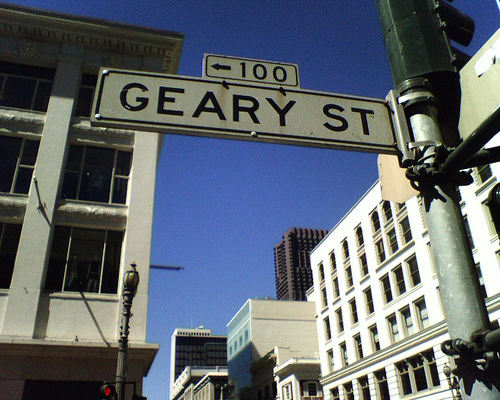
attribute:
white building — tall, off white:
[1, 2, 184, 399]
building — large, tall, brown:
[271, 225, 338, 300]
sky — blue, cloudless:
[153, 144, 280, 294]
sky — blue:
[38, 7, 426, 369]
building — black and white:
[171, 325, 226, 373]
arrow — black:
[203, 62, 245, 87]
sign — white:
[87, 40, 412, 160]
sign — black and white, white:
[74, 41, 417, 172]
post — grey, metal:
[382, 87, 497, 398]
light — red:
[79, 252, 163, 397]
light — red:
[93, 379, 116, 398]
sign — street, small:
[197, 46, 304, 91]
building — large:
[298, 131, 499, 398]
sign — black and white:
[86, 48, 419, 168]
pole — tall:
[352, 10, 498, 389]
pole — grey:
[112, 293, 134, 398]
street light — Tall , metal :
[115, 258, 142, 398]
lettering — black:
[113, 80, 378, 136]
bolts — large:
[404, 159, 434, 179]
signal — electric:
[97, 378, 138, 398]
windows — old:
[2, 113, 139, 310]